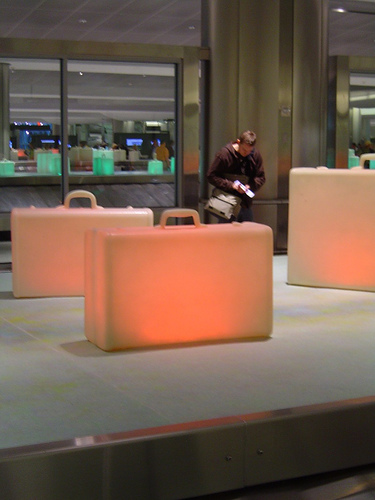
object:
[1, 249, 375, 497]
platform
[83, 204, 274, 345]
briefcase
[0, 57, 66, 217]
window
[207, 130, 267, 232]
person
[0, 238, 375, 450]
sidewalk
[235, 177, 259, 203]
object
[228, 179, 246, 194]
hand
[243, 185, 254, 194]
hand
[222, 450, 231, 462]
nails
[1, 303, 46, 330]
yellow paint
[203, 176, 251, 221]
bag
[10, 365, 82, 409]
paint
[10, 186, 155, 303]
briefcase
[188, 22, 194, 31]
lighting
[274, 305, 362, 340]
paint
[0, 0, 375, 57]
ceiling